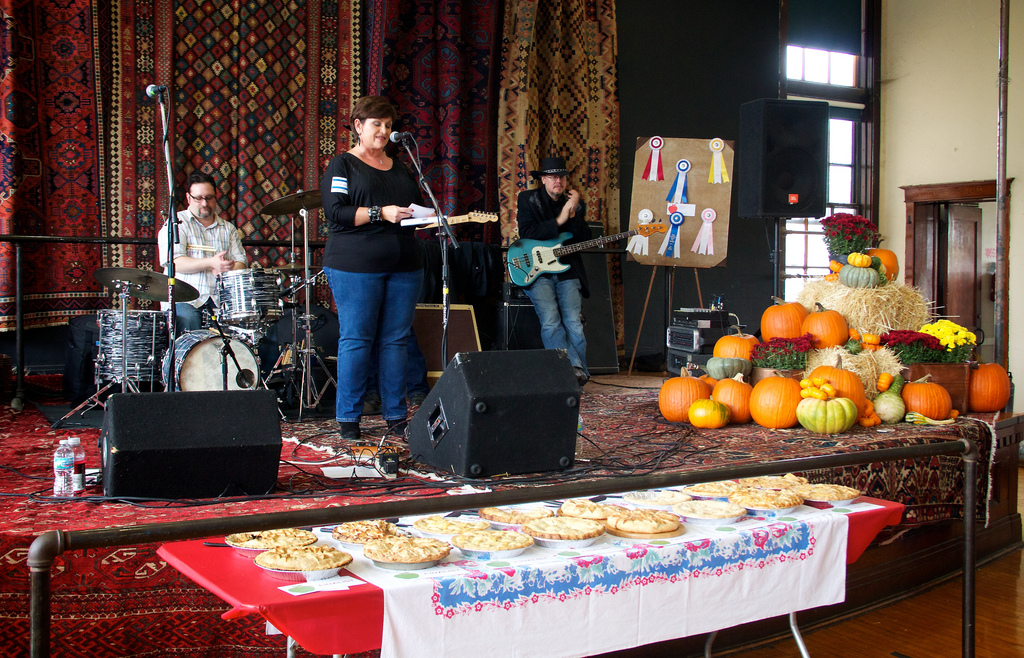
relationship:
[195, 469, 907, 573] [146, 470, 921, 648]
food on table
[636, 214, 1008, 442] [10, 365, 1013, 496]
pumpkins on stage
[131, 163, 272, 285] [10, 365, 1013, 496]
man on stage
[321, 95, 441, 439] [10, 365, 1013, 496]
people on stage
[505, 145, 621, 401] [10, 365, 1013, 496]
person on stage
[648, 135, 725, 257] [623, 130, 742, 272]
ribbons on board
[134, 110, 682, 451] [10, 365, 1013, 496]
people on stage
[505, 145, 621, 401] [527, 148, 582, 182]
person wearing a hat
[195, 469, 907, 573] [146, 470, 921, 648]
food on top table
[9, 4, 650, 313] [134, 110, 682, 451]
curtain behind people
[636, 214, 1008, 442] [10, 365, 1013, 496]
pumpkins are on stage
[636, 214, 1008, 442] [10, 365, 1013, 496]
pumpkins near stage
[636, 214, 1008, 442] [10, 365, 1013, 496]
pumpkins on top of stage